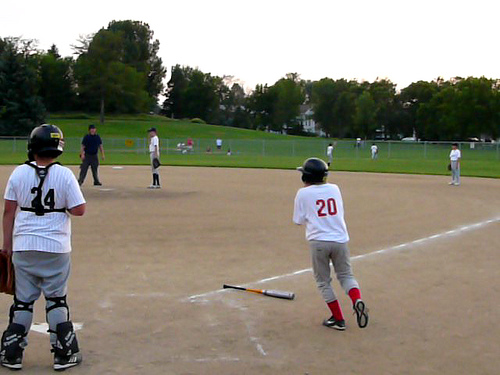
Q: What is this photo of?
A: A baseball game.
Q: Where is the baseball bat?
A: On the field.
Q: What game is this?
A: Baseball.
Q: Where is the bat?
A: On the first baseline.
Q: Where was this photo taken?
A: Baseball diamond in park.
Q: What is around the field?
A: Chain link fence.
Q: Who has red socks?
A: Player #20.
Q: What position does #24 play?
A: Catcher.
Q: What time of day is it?
A: Daytime.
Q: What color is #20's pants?
A: Gray.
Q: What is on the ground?
A: Bat.